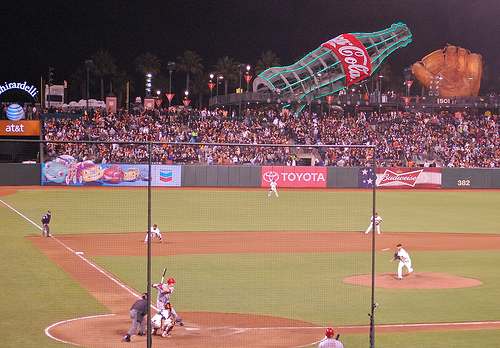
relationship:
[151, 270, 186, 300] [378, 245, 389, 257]
batter preparing to hit ball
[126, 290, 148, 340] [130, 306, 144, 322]
umpire wearing his grey uniform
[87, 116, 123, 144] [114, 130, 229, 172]
fans in stands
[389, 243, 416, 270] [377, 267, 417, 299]
pitcher on mound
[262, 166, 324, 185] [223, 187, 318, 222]
toyota sign near outfield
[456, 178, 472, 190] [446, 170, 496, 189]
numbers on fence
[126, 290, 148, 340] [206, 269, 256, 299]
umpire on field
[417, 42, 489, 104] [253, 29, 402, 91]
baseball glove near coke bottle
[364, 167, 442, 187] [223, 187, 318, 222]
budweiser sign near outfield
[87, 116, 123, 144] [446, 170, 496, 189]
fans near fence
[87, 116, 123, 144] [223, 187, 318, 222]
fans packed outfield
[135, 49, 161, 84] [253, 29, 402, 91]
palm tree near coke bottle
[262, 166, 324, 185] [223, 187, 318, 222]
toyota sign close to outfield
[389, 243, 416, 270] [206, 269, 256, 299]
pitcher playing on field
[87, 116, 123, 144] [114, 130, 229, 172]
fans sitting near stands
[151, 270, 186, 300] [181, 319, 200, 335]
batter at home plate